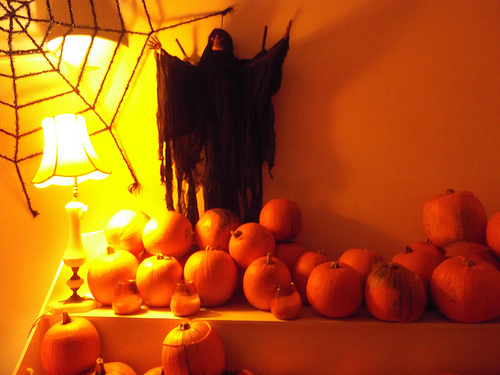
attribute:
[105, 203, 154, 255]
pumpkin — orange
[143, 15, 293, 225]
cloak — creepy, gauzy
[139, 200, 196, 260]
pumpkin — orange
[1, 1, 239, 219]
web — black, decoration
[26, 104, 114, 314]
lamp — on, slender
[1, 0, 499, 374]
wall — orange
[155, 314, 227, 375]
pumpkin — cut, orange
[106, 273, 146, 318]
candle — out, unlit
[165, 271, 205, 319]
candle — out, unlit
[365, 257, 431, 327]
pumkin — imperfect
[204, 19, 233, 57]
head — skeletal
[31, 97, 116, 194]
shade — askew, glowing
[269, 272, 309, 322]
candle — out, unlit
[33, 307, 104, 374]
pumpkin — orange, decoration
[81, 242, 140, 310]
pumpkin — orange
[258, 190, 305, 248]
pumpkin — orange, decoration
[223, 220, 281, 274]
pumpkin — orange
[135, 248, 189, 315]
pumpkin — orange, decoration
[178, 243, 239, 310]
pumpkin — orange, decoration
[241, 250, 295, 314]
pumpkin — orange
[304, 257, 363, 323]
pumpkin — orange, decoration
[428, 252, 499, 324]
pumpkin — orange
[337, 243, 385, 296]
pumpkin — orange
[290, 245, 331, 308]
pumpkin — orange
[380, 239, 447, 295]
pumpkin — orange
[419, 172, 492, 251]
pumpkin — orange, decoration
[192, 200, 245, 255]
pumpkin — orange, decoration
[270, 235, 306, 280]
pumpkin — orange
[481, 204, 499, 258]
pumpkin — orange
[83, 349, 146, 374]
pumpkin — orange